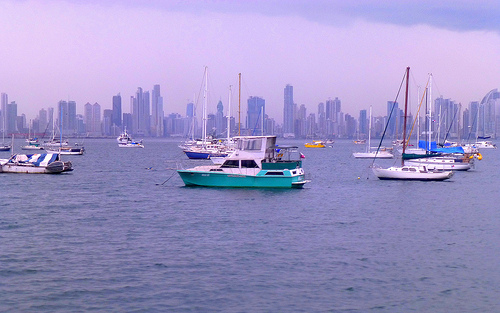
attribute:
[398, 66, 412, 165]
pole — red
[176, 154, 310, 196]
ship — blue